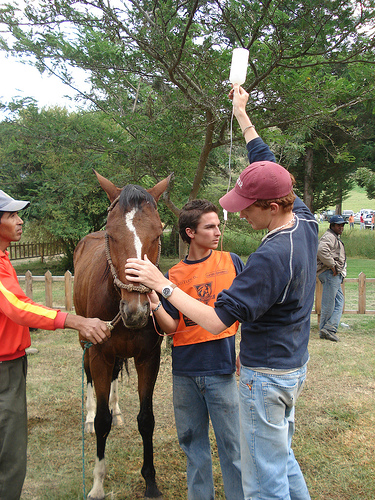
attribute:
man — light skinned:
[196, 171, 326, 399]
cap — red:
[222, 127, 317, 220]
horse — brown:
[65, 165, 193, 395]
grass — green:
[352, 252, 370, 286]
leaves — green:
[30, 39, 145, 111]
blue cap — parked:
[313, 195, 371, 236]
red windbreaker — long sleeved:
[1, 214, 53, 359]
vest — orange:
[168, 250, 238, 342]